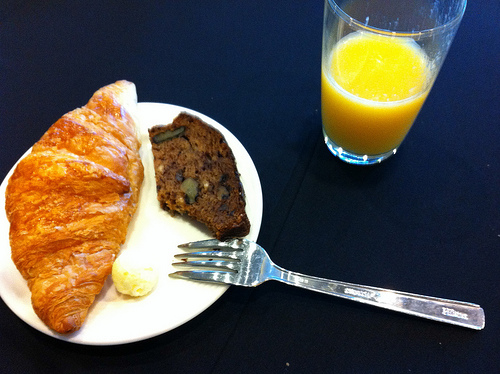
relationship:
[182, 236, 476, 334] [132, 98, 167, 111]
fork on top of plate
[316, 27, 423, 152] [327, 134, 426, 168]
juice inside of glass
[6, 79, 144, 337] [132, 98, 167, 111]
bread on top of plate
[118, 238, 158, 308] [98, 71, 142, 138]
butter next to croissant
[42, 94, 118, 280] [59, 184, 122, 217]
bread has nuts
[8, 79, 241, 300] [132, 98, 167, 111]
food on plate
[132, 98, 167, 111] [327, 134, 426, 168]
plate next to glass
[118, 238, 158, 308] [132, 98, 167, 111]
butter on top of plate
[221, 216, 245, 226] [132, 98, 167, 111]
fruit cake on top of plate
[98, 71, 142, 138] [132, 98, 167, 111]
croissant on top of plate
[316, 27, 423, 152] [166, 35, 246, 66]
juice on top of tablecloth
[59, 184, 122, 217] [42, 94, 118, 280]
nuts on top of bread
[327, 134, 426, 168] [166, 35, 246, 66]
glass on top of tablecloth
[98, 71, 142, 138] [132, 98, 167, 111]
croissant on plate